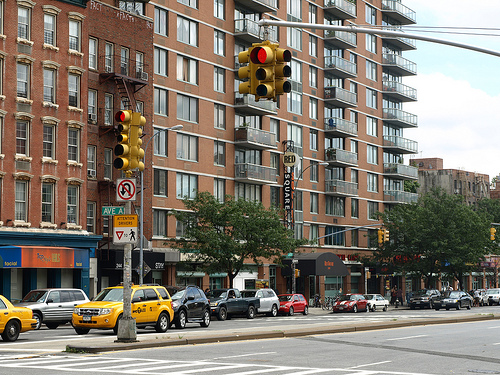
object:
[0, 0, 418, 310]
building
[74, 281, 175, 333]
taxi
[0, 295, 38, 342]
taxi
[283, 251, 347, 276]
awning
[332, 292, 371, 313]
car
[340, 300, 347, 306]
white stripes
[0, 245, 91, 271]
awning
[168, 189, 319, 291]
tree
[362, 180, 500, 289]
tree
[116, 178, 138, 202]
sign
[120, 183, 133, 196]
no u-turn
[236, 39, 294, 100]
traffic light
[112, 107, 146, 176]
traffic light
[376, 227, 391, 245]
traffic light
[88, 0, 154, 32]
graffiti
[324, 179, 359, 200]
balcony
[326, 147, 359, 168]
balcony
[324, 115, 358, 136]
balcony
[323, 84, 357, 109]
balcony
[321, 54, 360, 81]
balcony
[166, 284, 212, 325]
car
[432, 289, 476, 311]
car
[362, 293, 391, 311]
car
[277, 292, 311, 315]
car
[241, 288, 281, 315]
car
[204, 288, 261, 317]
car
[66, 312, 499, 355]
median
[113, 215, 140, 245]
sign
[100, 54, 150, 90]
balcony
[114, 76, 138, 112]
ladder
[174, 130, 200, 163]
window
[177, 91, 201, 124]
window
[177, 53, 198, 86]
window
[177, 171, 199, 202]
window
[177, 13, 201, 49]
window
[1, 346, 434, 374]
crosswalk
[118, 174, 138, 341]
pole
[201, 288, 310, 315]
line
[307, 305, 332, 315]
sidewalk